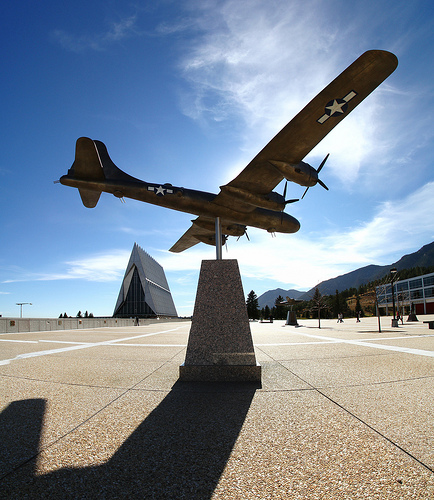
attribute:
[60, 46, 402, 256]
airplane — displayed, tall, statue, high, monument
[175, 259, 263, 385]
pedestal — granite, stone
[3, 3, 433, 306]
sky — blue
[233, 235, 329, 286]
cloud — white, wispy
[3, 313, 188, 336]
wall — concrete, low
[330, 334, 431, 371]
line — white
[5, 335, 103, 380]
line — white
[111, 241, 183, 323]
building — glass, triangular, pyramid-shaped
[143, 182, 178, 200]
logo — blue, white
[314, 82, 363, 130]
logo — blue, white